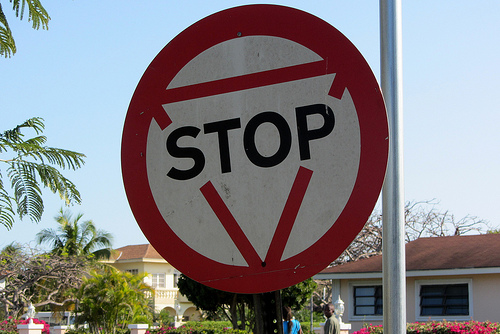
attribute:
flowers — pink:
[447, 321, 498, 332]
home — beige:
[307, 227, 497, 325]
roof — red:
[372, 233, 483, 264]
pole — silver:
[362, 14, 443, 314]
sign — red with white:
[82, 14, 410, 298]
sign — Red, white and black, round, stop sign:
[116, 1, 393, 298]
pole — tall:
[378, 0, 408, 333]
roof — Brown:
[317, 230, 499, 274]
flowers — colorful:
[3, 312, 51, 332]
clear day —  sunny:
[0, 3, 498, 259]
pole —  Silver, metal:
[369, 7, 444, 332]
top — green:
[323, 317, 340, 331]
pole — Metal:
[376, 0, 420, 333]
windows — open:
[354, 279, 473, 319]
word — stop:
[164, 101, 336, 181]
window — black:
[416, 279, 471, 316]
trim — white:
[413, 277, 474, 322]